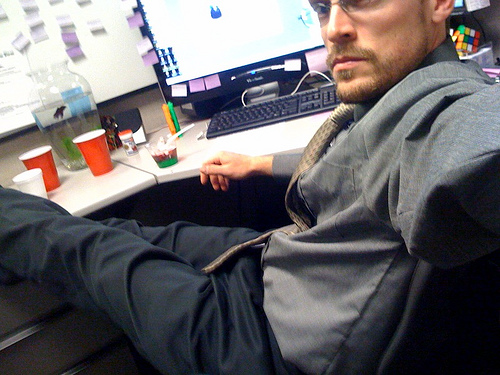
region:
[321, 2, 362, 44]
the nose of a man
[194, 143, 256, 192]
the hand of a man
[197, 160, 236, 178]
the thumb of a man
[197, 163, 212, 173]
the thumb nail of a man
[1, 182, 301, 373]
a pair of black pants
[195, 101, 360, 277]
a brown neck tie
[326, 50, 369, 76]
the mouth of a man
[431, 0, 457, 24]
the ear of a man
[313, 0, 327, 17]
the eye of a man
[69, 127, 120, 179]
a red and white cup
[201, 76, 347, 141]
a black computer keyboard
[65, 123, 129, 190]
orange disposable plastic cup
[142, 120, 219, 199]
red and green parfait dessert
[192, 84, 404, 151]
black keyboard on desk top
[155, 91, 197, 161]
yellow and green highlighters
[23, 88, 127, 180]
black Beta fish in clear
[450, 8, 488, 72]
Rubics cube set in corner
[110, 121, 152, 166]
white bottle of fish food with orange lid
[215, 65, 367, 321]
mans printed tie with gold and gray print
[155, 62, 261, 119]
small purpe post its on bottom of computer monitor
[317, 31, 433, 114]
man with beard and moustache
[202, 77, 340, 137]
Keyboard on top of desk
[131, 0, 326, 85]
computer monitor on desktop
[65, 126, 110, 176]
Red plastic cup sitting on desktop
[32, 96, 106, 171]
small fish bowel sitting on desktop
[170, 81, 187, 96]
white note-it sticking to bottom of monitor screen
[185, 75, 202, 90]
pink note-it sticking to bottom of monitor screen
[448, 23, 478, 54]
rubix cube sitting on desk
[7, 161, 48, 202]
white drinking water cup sitting on desk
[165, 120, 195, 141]
spoon in ice cream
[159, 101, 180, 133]
yellow and green markit sitting on desk top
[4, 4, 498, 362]
a man with his feet up on the desk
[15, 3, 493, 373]
a man wearing a suit and tie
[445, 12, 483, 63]
an unsolved rubix cube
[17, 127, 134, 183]
two red drinking cups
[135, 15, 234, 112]
purple and white sticky notes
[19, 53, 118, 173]
a clear vase with a fish in it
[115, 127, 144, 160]
a container of fish food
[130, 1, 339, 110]
a computer monitor that is on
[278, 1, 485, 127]
a man wearing glasses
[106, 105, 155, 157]
a silver and black speaker